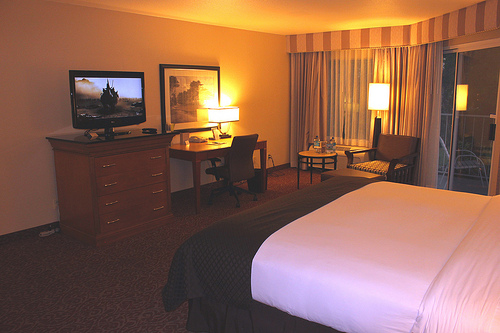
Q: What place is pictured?
A: It is a hotel room.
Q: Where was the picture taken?
A: It was taken at the hotel room.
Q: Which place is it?
A: It is a hotel room.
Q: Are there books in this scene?
A: No, there are no books.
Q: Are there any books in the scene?
A: No, there are no books.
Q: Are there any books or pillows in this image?
A: No, there are no books or pillows.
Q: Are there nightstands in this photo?
A: No, there are no nightstands.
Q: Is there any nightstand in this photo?
A: No, there are no nightstands.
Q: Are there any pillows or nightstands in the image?
A: No, there are no nightstands or pillows.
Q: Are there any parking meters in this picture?
A: No, there are no parking meters.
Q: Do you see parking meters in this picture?
A: No, there are no parking meters.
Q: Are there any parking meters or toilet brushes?
A: No, there are no parking meters or toilet brushes.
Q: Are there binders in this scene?
A: No, there are no binders.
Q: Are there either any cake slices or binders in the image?
A: No, there are no binders or cake slices.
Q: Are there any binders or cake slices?
A: No, there are no binders or cake slices.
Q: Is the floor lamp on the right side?
A: Yes, the floor lamp is on the right of the image.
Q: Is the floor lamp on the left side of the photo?
A: No, the floor lamp is on the right of the image.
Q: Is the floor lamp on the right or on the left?
A: The floor lamp is on the right of the image.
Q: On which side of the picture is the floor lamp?
A: The floor lamp is on the right of the image.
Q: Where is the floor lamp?
A: The floor lamp is in the hotel room.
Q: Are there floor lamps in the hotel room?
A: Yes, there is a floor lamp in the hotel room.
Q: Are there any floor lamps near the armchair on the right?
A: Yes, there is a floor lamp near the armchair.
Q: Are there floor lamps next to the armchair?
A: Yes, there is a floor lamp next to the armchair.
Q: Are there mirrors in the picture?
A: No, there are no mirrors.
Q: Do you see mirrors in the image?
A: No, there are no mirrors.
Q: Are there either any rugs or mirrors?
A: No, there are no mirrors or rugs.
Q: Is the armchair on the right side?
A: Yes, the armchair is on the right of the image.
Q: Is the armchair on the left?
A: No, the armchair is on the right of the image.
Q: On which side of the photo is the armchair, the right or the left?
A: The armchair is on the right of the image.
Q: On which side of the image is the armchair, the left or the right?
A: The armchair is on the right of the image.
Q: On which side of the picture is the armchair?
A: The armchair is on the right of the image.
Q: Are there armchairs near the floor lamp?
A: Yes, there is an armchair near the floor lamp.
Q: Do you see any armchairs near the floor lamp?
A: Yes, there is an armchair near the floor lamp.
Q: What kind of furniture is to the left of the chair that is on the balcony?
A: The piece of furniture is an armchair.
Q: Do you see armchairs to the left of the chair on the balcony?
A: Yes, there is an armchair to the left of the chair.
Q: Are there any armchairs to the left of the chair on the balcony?
A: Yes, there is an armchair to the left of the chair.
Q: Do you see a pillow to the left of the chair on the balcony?
A: No, there is an armchair to the left of the chair.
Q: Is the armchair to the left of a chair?
A: Yes, the armchair is to the left of a chair.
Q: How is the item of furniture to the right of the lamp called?
A: The piece of furniture is an armchair.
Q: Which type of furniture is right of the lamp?
A: The piece of furniture is an armchair.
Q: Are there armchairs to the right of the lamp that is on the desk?
A: Yes, there is an armchair to the right of the lamp.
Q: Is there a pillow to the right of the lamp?
A: No, there is an armchair to the right of the lamp.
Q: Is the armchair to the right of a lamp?
A: Yes, the armchair is to the right of a lamp.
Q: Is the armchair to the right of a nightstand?
A: No, the armchair is to the right of a lamp.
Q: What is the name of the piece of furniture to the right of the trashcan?
A: The piece of furniture is an armchair.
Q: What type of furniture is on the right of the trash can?
A: The piece of furniture is an armchair.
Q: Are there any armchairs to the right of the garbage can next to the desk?
A: Yes, there is an armchair to the right of the garbage bin.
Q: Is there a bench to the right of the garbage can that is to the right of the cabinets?
A: No, there is an armchair to the right of the trash can.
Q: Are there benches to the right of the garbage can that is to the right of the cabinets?
A: No, there is an armchair to the right of the trash can.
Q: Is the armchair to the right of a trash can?
A: Yes, the armchair is to the right of a trash can.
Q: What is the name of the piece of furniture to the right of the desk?
A: The piece of furniture is an armchair.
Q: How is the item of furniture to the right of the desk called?
A: The piece of furniture is an armchair.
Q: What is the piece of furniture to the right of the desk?
A: The piece of furniture is an armchair.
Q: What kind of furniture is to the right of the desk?
A: The piece of furniture is an armchair.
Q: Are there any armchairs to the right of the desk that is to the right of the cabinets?
A: Yes, there is an armchair to the right of the desk.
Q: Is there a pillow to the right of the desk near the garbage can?
A: No, there is an armchair to the right of the desk.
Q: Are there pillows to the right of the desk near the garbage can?
A: No, there is an armchair to the right of the desk.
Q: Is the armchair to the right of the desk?
A: Yes, the armchair is to the right of the desk.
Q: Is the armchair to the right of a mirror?
A: No, the armchair is to the right of the desk.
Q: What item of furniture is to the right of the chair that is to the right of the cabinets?
A: The piece of furniture is an armchair.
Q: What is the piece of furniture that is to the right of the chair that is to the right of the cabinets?
A: The piece of furniture is an armchair.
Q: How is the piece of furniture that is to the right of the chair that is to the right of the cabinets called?
A: The piece of furniture is an armchair.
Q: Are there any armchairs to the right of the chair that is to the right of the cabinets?
A: Yes, there is an armchair to the right of the chair.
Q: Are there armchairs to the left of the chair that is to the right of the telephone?
A: No, the armchair is to the right of the chair.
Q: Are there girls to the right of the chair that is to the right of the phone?
A: No, there is an armchair to the right of the chair.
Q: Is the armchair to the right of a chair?
A: Yes, the armchair is to the right of a chair.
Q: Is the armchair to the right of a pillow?
A: No, the armchair is to the right of a chair.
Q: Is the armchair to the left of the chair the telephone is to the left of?
A: No, the armchair is to the right of the chair.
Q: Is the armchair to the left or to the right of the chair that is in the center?
A: The armchair is to the right of the chair.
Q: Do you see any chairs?
A: Yes, there is a chair.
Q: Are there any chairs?
A: Yes, there is a chair.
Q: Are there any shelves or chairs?
A: Yes, there is a chair.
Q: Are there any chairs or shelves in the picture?
A: Yes, there is a chair.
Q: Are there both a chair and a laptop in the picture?
A: No, there is a chair but no laptops.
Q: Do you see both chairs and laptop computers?
A: No, there is a chair but no laptops.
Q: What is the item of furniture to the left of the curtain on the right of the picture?
A: The piece of furniture is a chair.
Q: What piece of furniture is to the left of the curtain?
A: The piece of furniture is a chair.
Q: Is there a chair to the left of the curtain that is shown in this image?
A: Yes, there is a chair to the left of the curtain.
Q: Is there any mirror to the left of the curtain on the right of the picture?
A: No, there is a chair to the left of the curtain.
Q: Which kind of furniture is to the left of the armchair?
A: The piece of furniture is a chair.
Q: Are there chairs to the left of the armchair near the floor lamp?
A: Yes, there is a chair to the left of the armchair.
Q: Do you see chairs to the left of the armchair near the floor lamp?
A: Yes, there is a chair to the left of the armchair.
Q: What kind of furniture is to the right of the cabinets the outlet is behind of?
A: The piece of furniture is a chair.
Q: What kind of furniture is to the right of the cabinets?
A: The piece of furniture is a chair.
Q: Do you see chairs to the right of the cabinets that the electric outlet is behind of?
A: Yes, there is a chair to the right of the cabinets.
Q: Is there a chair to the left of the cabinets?
A: No, the chair is to the right of the cabinets.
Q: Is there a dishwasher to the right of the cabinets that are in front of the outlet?
A: No, there is a chair to the right of the cabinets.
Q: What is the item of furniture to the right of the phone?
A: The piece of furniture is a chair.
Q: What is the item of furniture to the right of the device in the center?
A: The piece of furniture is a chair.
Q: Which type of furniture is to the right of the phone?
A: The piece of furniture is a chair.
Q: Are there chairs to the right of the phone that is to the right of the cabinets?
A: Yes, there is a chair to the right of the telephone.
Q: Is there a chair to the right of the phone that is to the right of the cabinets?
A: Yes, there is a chair to the right of the telephone.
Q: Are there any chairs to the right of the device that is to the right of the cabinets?
A: Yes, there is a chair to the right of the telephone.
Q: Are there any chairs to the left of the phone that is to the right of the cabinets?
A: No, the chair is to the right of the phone.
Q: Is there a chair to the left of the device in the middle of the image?
A: No, the chair is to the right of the phone.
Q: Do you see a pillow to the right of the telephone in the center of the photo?
A: No, there is a chair to the right of the phone.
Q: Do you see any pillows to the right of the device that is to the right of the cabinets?
A: No, there is a chair to the right of the phone.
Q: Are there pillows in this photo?
A: No, there are no pillows.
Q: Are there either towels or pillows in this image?
A: No, there are no pillows or towels.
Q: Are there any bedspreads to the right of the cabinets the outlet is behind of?
A: Yes, there is a bedspread to the right of the cabinets.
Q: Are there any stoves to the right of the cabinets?
A: No, there is a bedspread to the right of the cabinets.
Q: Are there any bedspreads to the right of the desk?
A: Yes, there is a bedspread to the right of the desk.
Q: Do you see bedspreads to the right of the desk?
A: Yes, there is a bedspread to the right of the desk.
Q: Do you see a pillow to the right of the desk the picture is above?
A: No, there is a bedspread to the right of the desk.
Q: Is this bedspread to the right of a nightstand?
A: No, the bedspread is to the right of the desk.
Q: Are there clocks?
A: No, there are no clocks.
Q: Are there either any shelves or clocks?
A: No, there are no clocks or shelves.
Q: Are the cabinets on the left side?
A: Yes, the cabinets are on the left of the image.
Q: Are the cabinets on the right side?
A: No, the cabinets are on the left of the image.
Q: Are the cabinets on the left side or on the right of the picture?
A: The cabinets are on the left of the image.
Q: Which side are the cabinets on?
A: The cabinets are on the left of the image.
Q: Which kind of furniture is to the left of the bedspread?
A: The pieces of furniture are cabinets.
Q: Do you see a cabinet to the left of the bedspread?
A: Yes, there are cabinets to the left of the bedspread.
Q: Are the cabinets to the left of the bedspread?
A: Yes, the cabinets are to the left of the bedspread.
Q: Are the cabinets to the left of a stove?
A: No, the cabinets are to the left of the bedspread.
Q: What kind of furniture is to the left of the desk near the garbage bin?
A: The pieces of furniture are cabinets.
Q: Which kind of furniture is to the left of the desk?
A: The pieces of furniture are cabinets.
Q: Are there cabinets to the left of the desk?
A: Yes, there are cabinets to the left of the desk.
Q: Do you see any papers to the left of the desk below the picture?
A: No, there are cabinets to the left of the desk.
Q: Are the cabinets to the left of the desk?
A: Yes, the cabinets are to the left of the desk.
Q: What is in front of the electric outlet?
A: The cabinets are in front of the electric outlet.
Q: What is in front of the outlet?
A: The cabinets are in front of the electric outlet.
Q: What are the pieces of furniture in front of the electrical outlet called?
A: The pieces of furniture are cabinets.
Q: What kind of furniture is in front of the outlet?
A: The pieces of furniture are cabinets.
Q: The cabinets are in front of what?
A: The cabinets are in front of the power outlet.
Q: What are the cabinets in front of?
A: The cabinets are in front of the power outlet.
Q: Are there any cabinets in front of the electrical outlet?
A: Yes, there are cabinets in front of the electrical outlet.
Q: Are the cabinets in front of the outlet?
A: Yes, the cabinets are in front of the outlet.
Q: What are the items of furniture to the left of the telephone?
A: The pieces of furniture are cabinets.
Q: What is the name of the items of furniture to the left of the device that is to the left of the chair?
A: The pieces of furniture are cabinets.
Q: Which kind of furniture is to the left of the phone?
A: The pieces of furniture are cabinets.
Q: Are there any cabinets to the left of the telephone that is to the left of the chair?
A: Yes, there are cabinets to the left of the telephone.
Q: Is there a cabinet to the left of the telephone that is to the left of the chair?
A: Yes, there are cabinets to the left of the telephone.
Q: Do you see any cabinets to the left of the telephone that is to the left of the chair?
A: Yes, there are cabinets to the left of the telephone.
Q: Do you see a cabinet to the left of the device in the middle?
A: Yes, there are cabinets to the left of the telephone.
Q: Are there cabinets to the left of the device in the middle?
A: Yes, there are cabinets to the left of the telephone.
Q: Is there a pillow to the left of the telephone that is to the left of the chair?
A: No, there are cabinets to the left of the telephone.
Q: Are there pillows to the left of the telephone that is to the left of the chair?
A: No, there are cabinets to the left of the telephone.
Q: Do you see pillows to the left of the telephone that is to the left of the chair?
A: No, there are cabinets to the left of the telephone.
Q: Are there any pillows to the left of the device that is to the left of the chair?
A: No, there are cabinets to the left of the telephone.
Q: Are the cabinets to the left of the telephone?
A: Yes, the cabinets are to the left of the telephone.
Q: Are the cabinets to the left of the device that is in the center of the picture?
A: Yes, the cabinets are to the left of the telephone.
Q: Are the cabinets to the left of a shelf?
A: No, the cabinets are to the left of the telephone.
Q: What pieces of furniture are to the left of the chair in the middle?
A: The pieces of furniture are cabinets.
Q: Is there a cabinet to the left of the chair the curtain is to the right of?
A: Yes, there are cabinets to the left of the chair.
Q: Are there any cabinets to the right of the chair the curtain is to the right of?
A: No, the cabinets are to the left of the chair.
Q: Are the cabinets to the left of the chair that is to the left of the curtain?
A: Yes, the cabinets are to the left of the chair.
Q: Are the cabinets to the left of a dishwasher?
A: No, the cabinets are to the left of the chair.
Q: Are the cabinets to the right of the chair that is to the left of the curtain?
A: No, the cabinets are to the left of the chair.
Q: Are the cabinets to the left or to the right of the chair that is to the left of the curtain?
A: The cabinets are to the left of the chair.